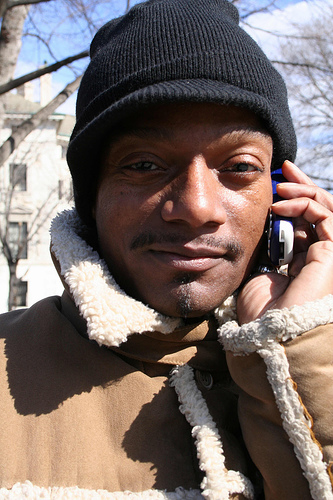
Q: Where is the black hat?
A: On the man's head.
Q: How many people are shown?
A: One.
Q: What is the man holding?
A: A phone.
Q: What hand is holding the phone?
A: Left.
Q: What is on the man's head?
A: A stocking cap.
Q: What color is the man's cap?
A: Black.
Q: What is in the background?
A: A building.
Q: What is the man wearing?
A: A coat.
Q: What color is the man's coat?
A: Tan.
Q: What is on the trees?
A: Nothing.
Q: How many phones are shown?
A: One.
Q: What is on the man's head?
A: Beanie.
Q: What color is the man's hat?
A: Black.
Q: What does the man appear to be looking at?
A: The camera.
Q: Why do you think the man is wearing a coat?
A: Cold out.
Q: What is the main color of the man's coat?
A: Brown.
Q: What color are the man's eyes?
A: Brown.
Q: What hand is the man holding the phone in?
A: Left.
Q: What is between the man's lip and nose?
A: A moustache.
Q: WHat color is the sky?
A: Blue.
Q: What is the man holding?
A: A cellphone.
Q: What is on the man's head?
A: Knit cap.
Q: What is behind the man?
A: Building.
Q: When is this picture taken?
A: Day time.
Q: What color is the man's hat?
A: Black.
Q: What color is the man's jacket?
A: Tan.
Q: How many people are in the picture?
A: One.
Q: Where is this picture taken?
A: Outside a building.